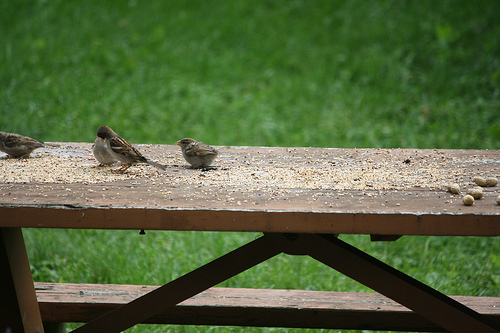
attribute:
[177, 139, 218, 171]
bird — brown, small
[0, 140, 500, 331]
picnic table — wooden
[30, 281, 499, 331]
bench — brown, wooden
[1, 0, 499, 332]
lawn — green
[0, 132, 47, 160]
bird — small